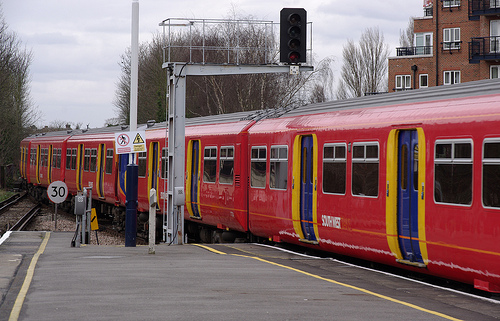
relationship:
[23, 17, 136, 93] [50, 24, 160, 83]
clouds in sky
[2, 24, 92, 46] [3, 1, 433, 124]
cloud in sky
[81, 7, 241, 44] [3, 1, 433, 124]
cloud in sky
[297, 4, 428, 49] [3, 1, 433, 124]
cloud in sky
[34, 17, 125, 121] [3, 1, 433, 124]
white clouds in sky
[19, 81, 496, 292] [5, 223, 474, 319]
train next to platform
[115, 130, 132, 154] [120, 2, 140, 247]
sign on pole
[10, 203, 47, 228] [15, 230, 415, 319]
rails on platform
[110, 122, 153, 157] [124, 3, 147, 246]
signs on pole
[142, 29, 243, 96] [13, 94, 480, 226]
tree behind train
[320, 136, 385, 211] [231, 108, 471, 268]
windows on train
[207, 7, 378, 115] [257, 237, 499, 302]
signal over track